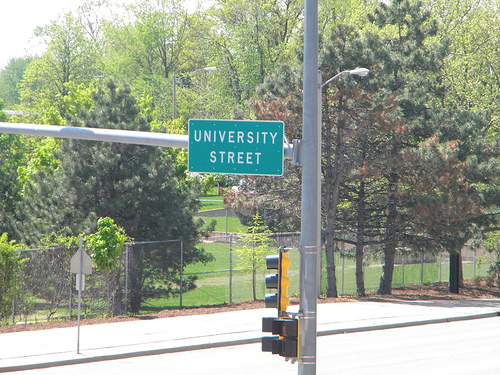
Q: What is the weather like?
A: It is clear.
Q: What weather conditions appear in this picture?
A: It is clear.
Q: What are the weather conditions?
A: It is clear.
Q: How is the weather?
A: It is clear.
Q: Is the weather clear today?
A: Yes, it is clear.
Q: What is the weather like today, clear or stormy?
A: It is clear.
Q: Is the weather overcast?
A: No, it is clear.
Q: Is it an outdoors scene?
A: Yes, it is outdoors.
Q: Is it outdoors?
A: Yes, it is outdoors.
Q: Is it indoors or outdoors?
A: It is outdoors.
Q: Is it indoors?
A: No, it is outdoors.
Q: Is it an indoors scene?
A: No, it is outdoors.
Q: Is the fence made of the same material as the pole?
A: Yes, both the fence and the pole are made of metal.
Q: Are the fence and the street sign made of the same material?
A: Yes, both the fence and the street sign are made of metal.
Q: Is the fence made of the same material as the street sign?
A: Yes, both the fence and the street sign are made of metal.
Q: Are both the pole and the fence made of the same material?
A: Yes, both the pole and the fence are made of metal.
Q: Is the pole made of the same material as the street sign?
A: Yes, both the pole and the street sign are made of metal.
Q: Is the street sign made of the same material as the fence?
A: Yes, both the street sign and the fence are made of metal.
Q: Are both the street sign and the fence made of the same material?
A: Yes, both the street sign and the fence are made of metal.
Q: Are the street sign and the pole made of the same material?
A: Yes, both the street sign and the pole are made of metal.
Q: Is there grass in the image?
A: Yes, there is grass.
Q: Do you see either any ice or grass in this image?
A: Yes, there is grass.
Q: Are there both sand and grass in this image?
A: No, there is grass but no sand.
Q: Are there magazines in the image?
A: No, there are no magazines.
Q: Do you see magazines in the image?
A: No, there are no magazines.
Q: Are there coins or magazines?
A: No, there are no magazines or coins.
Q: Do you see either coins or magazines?
A: No, there are no magazines or coins.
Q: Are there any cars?
A: No, there are no cars.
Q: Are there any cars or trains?
A: No, there are no cars or trains.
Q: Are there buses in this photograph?
A: No, there are no buses.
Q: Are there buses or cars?
A: No, there are no buses or cars.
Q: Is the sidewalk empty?
A: Yes, the sidewalk is empty.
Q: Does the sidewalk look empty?
A: Yes, the sidewalk is empty.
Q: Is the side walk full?
A: No, the side walk is empty.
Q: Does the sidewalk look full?
A: No, the sidewalk is empty.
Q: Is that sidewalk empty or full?
A: The sidewalk is empty.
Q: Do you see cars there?
A: No, there are no cars.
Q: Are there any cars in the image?
A: No, there are no cars.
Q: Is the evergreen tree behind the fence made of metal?
A: Yes, the tree is behind the fence.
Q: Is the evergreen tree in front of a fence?
A: No, the tree is behind a fence.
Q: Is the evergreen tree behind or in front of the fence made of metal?
A: The tree is behind the fence.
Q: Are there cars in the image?
A: No, there are no cars.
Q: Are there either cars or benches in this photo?
A: No, there are no cars or benches.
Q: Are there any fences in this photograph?
A: Yes, there is a fence.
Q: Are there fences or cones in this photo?
A: Yes, there is a fence.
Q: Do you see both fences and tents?
A: No, there is a fence but no tents.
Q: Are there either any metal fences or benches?
A: Yes, there is a metal fence.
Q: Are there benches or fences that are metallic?
A: Yes, the fence is metallic.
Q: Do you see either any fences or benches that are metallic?
A: Yes, the fence is metallic.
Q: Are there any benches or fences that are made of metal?
A: Yes, the fence is made of metal.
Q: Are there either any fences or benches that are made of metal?
A: Yes, the fence is made of metal.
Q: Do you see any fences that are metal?
A: Yes, there is a metal fence.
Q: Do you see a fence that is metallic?
A: Yes, there is a fence that is metallic.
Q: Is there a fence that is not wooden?
A: Yes, there is a metallic fence.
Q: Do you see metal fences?
A: Yes, there is a fence that is made of metal.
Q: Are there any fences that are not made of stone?
A: Yes, there is a fence that is made of metal.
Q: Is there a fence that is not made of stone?
A: Yes, there is a fence that is made of metal.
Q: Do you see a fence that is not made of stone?
A: Yes, there is a fence that is made of metal.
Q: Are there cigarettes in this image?
A: No, there are no cigarettes.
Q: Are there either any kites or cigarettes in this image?
A: No, there are no cigarettes or kites.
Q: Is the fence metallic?
A: Yes, the fence is metallic.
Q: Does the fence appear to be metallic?
A: Yes, the fence is metallic.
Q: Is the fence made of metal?
A: Yes, the fence is made of metal.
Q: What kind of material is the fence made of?
A: The fence is made of metal.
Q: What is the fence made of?
A: The fence is made of metal.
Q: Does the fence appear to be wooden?
A: No, the fence is metallic.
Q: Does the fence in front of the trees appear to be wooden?
A: No, the fence is metallic.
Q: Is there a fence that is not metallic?
A: No, there is a fence but it is metallic.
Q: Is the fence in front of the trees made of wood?
A: No, the fence is made of metal.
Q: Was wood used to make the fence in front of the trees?
A: No, the fence is made of metal.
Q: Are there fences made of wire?
A: No, there is a fence but it is made of metal.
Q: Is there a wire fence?
A: No, there is a fence but it is made of metal.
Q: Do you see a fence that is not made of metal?
A: No, there is a fence but it is made of metal.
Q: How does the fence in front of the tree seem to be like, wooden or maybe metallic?
A: The fence is metallic.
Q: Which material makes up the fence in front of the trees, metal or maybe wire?
A: The fence is made of metal.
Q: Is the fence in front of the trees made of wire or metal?
A: The fence is made of metal.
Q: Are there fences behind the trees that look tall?
A: No, the fence is in front of the trees.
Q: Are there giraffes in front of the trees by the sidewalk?
A: No, there is a fence in front of the trees.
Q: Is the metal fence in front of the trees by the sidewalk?
A: Yes, the fence is in front of the trees.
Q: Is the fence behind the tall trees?
A: No, the fence is in front of the trees.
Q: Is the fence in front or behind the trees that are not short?
A: The fence is in front of the trees.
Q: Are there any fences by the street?
A: Yes, there is a fence by the street.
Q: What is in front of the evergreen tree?
A: The fence is in front of the tree.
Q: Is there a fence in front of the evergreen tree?
A: Yes, there is a fence in front of the tree.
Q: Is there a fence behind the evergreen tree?
A: No, the fence is in front of the tree.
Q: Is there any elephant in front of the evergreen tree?
A: No, there is a fence in front of the tree.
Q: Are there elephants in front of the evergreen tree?
A: No, there is a fence in front of the tree.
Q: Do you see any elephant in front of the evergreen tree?
A: No, there is a fence in front of the tree.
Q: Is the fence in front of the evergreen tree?
A: Yes, the fence is in front of the tree.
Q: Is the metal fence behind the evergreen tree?
A: No, the fence is in front of the tree.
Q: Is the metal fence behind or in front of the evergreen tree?
A: The fence is in front of the tree.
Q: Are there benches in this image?
A: No, there are no benches.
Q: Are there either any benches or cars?
A: No, there are no benches or cars.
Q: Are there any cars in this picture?
A: No, there are no cars.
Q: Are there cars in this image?
A: No, there are no cars.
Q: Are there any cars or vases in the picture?
A: No, there are no cars or vases.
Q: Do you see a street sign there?
A: Yes, there is a street sign.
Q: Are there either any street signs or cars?
A: Yes, there is a street sign.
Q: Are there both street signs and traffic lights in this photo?
A: Yes, there are both a street sign and a traffic light.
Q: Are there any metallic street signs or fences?
A: Yes, there is a metal street sign.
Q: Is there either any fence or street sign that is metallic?
A: Yes, the street sign is metallic.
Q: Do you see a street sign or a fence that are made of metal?
A: Yes, the street sign is made of metal.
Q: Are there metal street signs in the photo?
A: Yes, there is a metal street sign.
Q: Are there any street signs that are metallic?
A: Yes, there is a street sign that is metallic.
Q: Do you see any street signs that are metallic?
A: Yes, there is a street sign that is metallic.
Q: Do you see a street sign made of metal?
A: Yes, there is a street sign that is made of metal.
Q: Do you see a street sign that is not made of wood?
A: Yes, there is a street sign that is made of metal.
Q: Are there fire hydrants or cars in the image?
A: No, there are no cars or fire hydrants.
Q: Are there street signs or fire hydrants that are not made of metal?
A: No, there is a street sign but it is made of metal.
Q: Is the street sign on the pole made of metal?
A: Yes, the street sign is made of metal.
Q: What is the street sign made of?
A: The street sign is made of metal.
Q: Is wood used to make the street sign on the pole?
A: No, the street sign is made of metal.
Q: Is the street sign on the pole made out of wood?
A: No, the street sign is made of metal.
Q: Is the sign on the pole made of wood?
A: No, the street sign is made of metal.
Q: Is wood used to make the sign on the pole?
A: No, the street sign is made of metal.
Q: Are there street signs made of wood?
A: No, there is a street sign but it is made of metal.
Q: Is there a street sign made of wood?
A: No, there is a street sign but it is made of metal.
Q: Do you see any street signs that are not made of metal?
A: No, there is a street sign but it is made of metal.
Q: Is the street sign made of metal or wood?
A: The street sign is made of metal.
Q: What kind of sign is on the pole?
A: The sign is a street sign.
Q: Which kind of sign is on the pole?
A: The sign is a street sign.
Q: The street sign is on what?
A: The street sign is on the pole.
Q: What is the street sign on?
A: The street sign is on the pole.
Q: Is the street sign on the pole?
A: Yes, the street sign is on the pole.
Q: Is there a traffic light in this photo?
A: Yes, there is a traffic light.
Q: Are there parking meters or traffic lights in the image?
A: Yes, there is a traffic light.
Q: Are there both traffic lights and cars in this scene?
A: No, there is a traffic light but no cars.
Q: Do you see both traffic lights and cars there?
A: No, there is a traffic light but no cars.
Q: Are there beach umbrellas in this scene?
A: No, there are no beach umbrellas.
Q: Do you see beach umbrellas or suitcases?
A: No, there are no beach umbrellas or suitcases.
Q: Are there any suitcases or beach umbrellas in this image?
A: No, there are no beach umbrellas or suitcases.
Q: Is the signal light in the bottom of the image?
A: Yes, the signal light is in the bottom of the image.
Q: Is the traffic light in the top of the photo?
A: No, the traffic light is in the bottom of the image.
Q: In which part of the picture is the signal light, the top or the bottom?
A: The signal light is in the bottom of the image.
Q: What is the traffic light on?
A: The traffic light is on the pole.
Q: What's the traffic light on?
A: The traffic light is on the pole.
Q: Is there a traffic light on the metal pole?
A: Yes, there is a traffic light on the pole.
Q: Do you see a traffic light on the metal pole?
A: Yes, there is a traffic light on the pole.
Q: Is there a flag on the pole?
A: No, there is a traffic light on the pole.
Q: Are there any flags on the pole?
A: No, there is a traffic light on the pole.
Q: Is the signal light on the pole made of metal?
A: Yes, the signal light is on the pole.